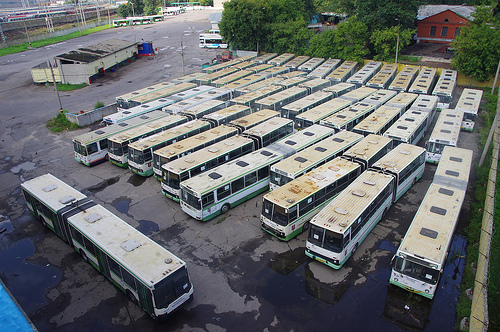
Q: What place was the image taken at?
A: It was taken at the parking lot.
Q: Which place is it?
A: It is a parking lot.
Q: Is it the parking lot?
A: Yes, it is the parking lot.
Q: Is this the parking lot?
A: Yes, it is the parking lot.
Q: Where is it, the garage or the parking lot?
A: It is the parking lot.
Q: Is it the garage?
A: No, it is the parking lot.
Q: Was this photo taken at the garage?
A: No, the picture was taken in the parking lot.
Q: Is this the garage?
A: No, it is the parking lot.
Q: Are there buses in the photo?
A: Yes, there is a bus.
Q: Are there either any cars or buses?
A: Yes, there is a bus.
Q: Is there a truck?
A: No, there are no trucks.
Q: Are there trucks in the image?
A: No, there are no trucks.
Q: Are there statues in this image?
A: No, there are no statues.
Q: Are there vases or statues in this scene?
A: No, there are no statues or vases.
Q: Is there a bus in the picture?
A: Yes, there is a bus.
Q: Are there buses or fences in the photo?
A: Yes, there is a bus.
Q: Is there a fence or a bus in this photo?
A: Yes, there is a bus.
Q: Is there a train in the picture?
A: No, there are no trains.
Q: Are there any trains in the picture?
A: No, there are no trains.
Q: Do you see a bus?
A: Yes, there is a bus.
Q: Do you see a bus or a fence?
A: Yes, there is a bus.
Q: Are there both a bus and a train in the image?
A: No, there is a bus but no trains.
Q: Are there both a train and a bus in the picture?
A: No, there is a bus but no trains.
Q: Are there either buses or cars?
A: Yes, there is a bus.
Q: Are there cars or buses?
A: Yes, there is a bus.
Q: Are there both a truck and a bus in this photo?
A: No, there is a bus but no trucks.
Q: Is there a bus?
A: Yes, there is a bus.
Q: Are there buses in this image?
A: Yes, there are buses.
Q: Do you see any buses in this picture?
A: Yes, there are buses.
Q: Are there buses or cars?
A: Yes, there are buses.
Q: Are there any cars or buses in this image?
A: Yes, there are buses.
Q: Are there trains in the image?
A: No, there are no trains.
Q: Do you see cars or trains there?
A: No, there are no trains or cars.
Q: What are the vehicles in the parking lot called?
A: The vehicles are buses.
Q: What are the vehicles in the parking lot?
A: The vehicles are buses.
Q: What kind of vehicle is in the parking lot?
A: The vehicles are buses.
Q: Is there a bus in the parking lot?
A: Yes, there are buses in the parking lot.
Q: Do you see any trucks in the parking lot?
A: No, there are buses in the parking lot.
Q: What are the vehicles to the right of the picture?
A: The vehicles are buses.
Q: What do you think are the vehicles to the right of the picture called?
A: The vehicles are buses.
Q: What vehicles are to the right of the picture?
A: The vehicles are buses.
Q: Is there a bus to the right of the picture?
A: Yes, there are buses to the right of the picture.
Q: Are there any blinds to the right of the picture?
A: No, there are buses to the right of the picture.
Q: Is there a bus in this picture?
A: Yes, there is a bus.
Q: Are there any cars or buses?
A: Yes, there is a bus.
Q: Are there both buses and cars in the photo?
A: No, there is a bus but no cars.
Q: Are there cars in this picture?
A: No, there are no cars.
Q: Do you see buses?
A: Yes, there is a bus.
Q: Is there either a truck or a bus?
A: Yes, there is a bus.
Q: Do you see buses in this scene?
A: Yes, there is a bus.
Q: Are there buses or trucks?
A: Yes, there is a bus.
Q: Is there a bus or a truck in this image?
A: Yes, there is a bus.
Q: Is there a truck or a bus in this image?
A: Yes, there is a bus.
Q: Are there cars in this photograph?
A: No, there are no cars.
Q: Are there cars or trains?
A: No, there are no cars or trains.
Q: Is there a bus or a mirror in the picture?
A: Yes, there is a bus.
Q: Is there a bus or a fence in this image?
A: Yes, there is a bus.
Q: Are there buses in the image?
A: Yes, there is a bus.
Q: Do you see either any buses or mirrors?
A: Yes, there is a bus.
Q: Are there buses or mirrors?
A: Yes, there is a bus.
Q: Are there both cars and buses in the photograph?
A: No, there is a bus but no cars.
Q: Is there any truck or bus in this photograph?
A: Yes, there is a bus.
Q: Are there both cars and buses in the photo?
A: No, there is a bus but no cars.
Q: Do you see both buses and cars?
A: No, there is a bus but no cars.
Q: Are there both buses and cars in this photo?
A: No, there is a bus but no cars.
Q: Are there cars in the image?
A: No, there are no cars.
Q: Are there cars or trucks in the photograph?
A: No, there are no cars or trucks.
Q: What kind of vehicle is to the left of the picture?
A: The vehicle is a bus.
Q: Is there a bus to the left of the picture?
A: Yes, there is a bus to the left of the picture.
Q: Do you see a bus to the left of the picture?
A: Yes, there is a bus to the left of the picture.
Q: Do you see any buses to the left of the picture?
A: Yes, there is a bus to the left of the picture.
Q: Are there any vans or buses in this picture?
A: Yes, there are buses.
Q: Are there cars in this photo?
A: No, there are no cars.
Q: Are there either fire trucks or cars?
A: No, there are no cars or fire trucks.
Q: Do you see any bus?
A: Yes, there is a bus.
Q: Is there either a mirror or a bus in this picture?
A: Yes, there is a bus.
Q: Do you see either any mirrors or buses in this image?
A: Yes, there is a bus.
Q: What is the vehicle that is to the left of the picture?
A: The vehicle is a bus.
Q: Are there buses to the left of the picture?
A: Yes, there is a bus to the left of the picture.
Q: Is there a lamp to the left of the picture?
A: No, there is a bus to the left of the picture.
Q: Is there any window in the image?
A: Yes, there are windows.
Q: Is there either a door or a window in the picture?
A: Yes, there are windows.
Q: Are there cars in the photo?
A: No, there are no cars.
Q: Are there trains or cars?
A: No, there are no cars or trains.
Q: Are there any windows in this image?
A: Yes, there are windows.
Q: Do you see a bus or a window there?
A: Yes, there are windows.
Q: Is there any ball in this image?
A: No, there are no balls.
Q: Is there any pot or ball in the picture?
A: No, there are no balls or pots.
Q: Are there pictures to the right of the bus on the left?
A: Yes, there is a picture to the right of the bus.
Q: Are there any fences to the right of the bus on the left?
A: No, there is a picture to the right of the bus.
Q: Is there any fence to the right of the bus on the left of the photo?
A: No, there is a picture to the right of the bus.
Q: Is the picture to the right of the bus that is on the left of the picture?
A: Yes, the picture is to the right of the bus.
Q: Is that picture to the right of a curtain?
A: No, the picture is to the right of the bus.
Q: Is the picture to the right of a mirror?
A: No, the picture is to the right of a bus.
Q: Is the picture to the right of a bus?
A: Yes, the picture is to the right of a bus.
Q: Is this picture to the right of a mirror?
A: No, the picture is to the right of a bus.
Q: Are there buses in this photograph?
A: Yes, there is a bus.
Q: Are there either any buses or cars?
A: Yes, there is a bus.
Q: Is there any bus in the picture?
A: Yes, there are buses.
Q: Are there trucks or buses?
A: Yes, there are buses.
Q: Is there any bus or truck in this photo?
A: Yes, there are buses.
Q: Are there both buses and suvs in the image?
A: No, there are buses but no suvs.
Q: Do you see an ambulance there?
A: No, there are no ambulances.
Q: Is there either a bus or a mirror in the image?
A: Yes, there is a bus.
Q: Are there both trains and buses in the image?
A: No, there is a bus but no trains.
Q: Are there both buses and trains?
A: No, there is a bus but no trains.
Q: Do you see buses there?
A: Yes, there is a bus.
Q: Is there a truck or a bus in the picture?
A: Yes, there is a bus.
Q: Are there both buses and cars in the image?
A: No, there is a bus but no cars.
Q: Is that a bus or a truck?
A: That is a bus.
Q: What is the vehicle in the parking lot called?
A: The vehicle is a bus.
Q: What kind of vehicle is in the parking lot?
A: The vehicle is a bus.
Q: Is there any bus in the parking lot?
A: Yes, there is a bus in the parking lot.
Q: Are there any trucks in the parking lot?
A: No, there is a bus in the parking lot.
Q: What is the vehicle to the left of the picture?
A: The vehicle is a bus.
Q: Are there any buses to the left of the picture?
A: Yes, there is a bus to the left of the picture.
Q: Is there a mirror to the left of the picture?
A: No, there is a bus to the left of the picture.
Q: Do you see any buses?
A: Yes, there is a bus.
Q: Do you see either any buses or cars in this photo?
A: Yes, there is a bus.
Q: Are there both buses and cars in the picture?
A: No, there is a bus but no cars.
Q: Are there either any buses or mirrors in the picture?
A: Yes, there is a bus.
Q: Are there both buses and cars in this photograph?
A: No, there is a bus but no cars.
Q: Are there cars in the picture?
A: No, there are no cars.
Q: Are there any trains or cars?
A: No, there are no cars or trains.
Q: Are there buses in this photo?
A: Yes, there is a bus.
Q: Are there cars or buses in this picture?
A: Yes, there is a bus.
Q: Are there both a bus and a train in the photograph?
A: No, there is a bus but no trains.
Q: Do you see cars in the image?
A: No, there are no cars.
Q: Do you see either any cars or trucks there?
A: No, there are no cars or trucks.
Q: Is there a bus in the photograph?
A: Yes, there is a bus.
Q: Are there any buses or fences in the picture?
A: Yes, there is a bus.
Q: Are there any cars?
A: No, there are no cars.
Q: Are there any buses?
A: Yes, there is a bus.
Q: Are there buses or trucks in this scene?
A: Yes, there is a bus.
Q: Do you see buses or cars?
A: Yes, there is a bus.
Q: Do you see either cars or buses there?
A: Yes, there is a bus.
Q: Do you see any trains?
A: No, there are no trains.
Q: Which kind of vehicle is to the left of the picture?
A: The vehicle is a bus.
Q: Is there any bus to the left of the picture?
A: Yes, there is a bus to the left of the picture.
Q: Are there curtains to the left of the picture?
A: No, there is a bus to the left of the picture.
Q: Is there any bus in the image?
A: Yes, there are buses.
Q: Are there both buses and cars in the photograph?
A: No, there are buses but no cars.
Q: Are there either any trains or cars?
A: No, there are no cars or trains.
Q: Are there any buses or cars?
A: Yes, there are buses.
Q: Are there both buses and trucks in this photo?
A: No, there are buses but no trucks.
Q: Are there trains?
A: No, there are no trains.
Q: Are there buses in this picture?
A: Yes, there are buses.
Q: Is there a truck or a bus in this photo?
A: Yes, there are buses.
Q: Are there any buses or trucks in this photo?
A: Yes, there are buses.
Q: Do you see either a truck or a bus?
A: Yes, there are buses.